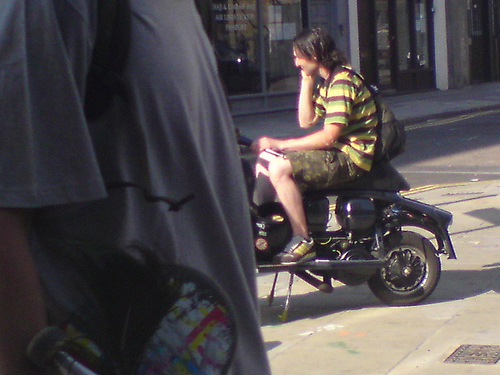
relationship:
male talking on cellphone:
[248, 26, 379, 265] [283, 46, 308, 79]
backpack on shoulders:
[318, 64, 411, 171] [311, 65, 357, 120]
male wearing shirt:
[248, 26, 379, 265] [307, 67, 377, 169]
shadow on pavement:
[268, 271, 496, 312] [271, 302, 498, 369]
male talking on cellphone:
[248, 26, 379, 265] [296, 60, 301, 72]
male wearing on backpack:
[248, 26, 379, 265] [342, 95, 411, 164]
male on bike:
[248, 26, 379, 265] [239, 132, 457, 307]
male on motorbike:
[248, 26, 379, 265] [232, 126, 457, 323]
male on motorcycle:
[248, 26, 379, 265] [237, 136, 457, 326]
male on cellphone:
[248, 26, 379, 265] [294, 58, 303, 71]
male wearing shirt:
[248, 26, 379, 265] [307, 69, 390, 165]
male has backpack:
[248, 26, 379, 265] [367, 81, 411, 172]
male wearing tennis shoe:
[248, 26, 379, 265] [274, 233, 317, 265]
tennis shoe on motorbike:
[272, 234, 318, 265] [252, 122, 455, 303]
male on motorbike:
[253, 32, 383, 263] [232, 126, 457, 323]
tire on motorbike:
[371, 224, 447, 310] [232, 126, 457, 323]